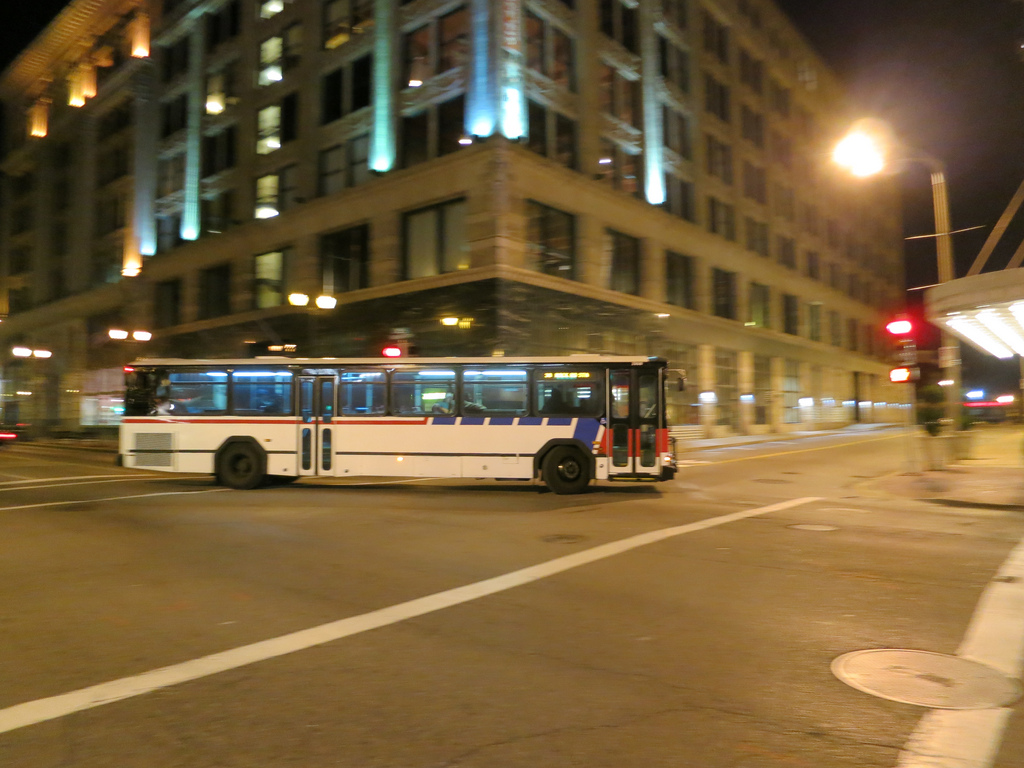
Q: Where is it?
A: This is at the city.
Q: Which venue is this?
A: This is a city.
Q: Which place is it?
A: It is a city.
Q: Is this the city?
A: Yes, it is the city.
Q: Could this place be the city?
A: Yes, it is the city.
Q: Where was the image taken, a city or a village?
A: It was taken at a city.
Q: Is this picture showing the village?
A: No, the picture is showing the city.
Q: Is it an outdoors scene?
A: Yes, it is outdoors.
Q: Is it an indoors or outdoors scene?
A: It is outdoors.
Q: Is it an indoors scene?
A: No, it is outdoors.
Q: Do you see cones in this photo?
A: No, there are no cones.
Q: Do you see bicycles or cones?
A: No, there are no cones or bicycles.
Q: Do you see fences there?
A: No, there are no fences.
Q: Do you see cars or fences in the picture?
A: No, there are no fences or cars.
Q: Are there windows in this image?
A: Yes, there is a window.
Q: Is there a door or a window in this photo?
A: Yes, there is a window.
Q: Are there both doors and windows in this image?
A: Yes, there are both a window and a door.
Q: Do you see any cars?
A: No, there are no cars.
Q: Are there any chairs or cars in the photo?
A: No, there are no cars or chairs.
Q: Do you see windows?
A: Yes, there is a window.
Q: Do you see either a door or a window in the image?
A: Yes, there is a window.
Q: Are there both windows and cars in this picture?
A: No, there is a window but no cars.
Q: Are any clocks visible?
A: No, there are no clocks.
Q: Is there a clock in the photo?
A: No, there are no clocks.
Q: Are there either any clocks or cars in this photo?
A: No, there are no clocks or cars.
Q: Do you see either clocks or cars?
A: No, there are no clocks or cars.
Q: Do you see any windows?
A: Yes, there is a window.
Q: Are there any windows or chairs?
A: Yes, there is a window.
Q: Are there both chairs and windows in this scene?
A: No, there is a window but no chairs.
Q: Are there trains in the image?
A: No, there are no trains.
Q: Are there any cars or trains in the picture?
A: No, there are no trains or cars.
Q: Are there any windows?
A: Yes, there is a window.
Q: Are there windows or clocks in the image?
A: Yes, there is a window.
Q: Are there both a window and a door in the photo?
A: Yes, there are both a window and a door.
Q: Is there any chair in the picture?
A: No, there are no chairs.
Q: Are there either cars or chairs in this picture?
A: No, there are no chairs or cars.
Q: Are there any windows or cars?
A: Yes, there is a window.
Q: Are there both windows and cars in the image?
A: No, there is a window but no cars.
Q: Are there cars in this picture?
A: No, there are no cars.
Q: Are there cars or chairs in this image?
A: No, there are no cars or chairs.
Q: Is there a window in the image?
A: Yes, there is a window.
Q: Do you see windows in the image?
A: Yes, there is a window.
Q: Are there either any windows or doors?
A: Yes, there is a window.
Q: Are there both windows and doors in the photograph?
A: Yes, there are both a window and a door.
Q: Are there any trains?
A: No, there are no trains.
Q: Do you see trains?
A: No, there are no trains.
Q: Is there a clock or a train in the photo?
A: No, there are no trains or clocks.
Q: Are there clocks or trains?
A: No, there are no trains or clocks.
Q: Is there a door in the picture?
A: Yes, there is a door.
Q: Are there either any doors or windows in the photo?
A: Yes, there is a door.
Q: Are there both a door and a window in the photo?
A: Yes, there are both a door and a window.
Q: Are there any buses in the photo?
A: Yes, there is a bus.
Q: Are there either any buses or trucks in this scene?
A: Yes, there is a bus.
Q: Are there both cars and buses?
A: No, there is a bus but no cars.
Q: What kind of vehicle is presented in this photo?
A: The vehicle is a bus.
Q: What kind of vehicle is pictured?
A: The vehicle is a bus.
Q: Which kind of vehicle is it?
A: The vehicle is a bus.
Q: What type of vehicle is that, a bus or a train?
A: This is a bus.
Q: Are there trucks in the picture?
A: No, there are no trucks.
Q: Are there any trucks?
A: No, there are no trucks.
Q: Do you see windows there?
A: Yes, there is a window.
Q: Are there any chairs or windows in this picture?
A: Yes, there is a window.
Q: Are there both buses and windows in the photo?
A: Yes, there are both a window and a bus.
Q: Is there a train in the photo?
A: No, there are no trains.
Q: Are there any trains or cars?
A: No, there are no trains or cars.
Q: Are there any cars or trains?
A: No, there are no trains or cars.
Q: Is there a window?
A: Yes, there is a window.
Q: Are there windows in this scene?
A: Yes, there is a window.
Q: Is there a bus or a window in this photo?
A: Yes, there is a window.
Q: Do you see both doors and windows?
A: Yes, there are both a window and a door.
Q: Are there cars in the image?
A: No, there are no cars.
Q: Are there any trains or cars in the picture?
A: No, there are no cars or trains.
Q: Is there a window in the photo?
A: Yes, there is a window.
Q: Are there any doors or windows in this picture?
A: Yes, there is a window.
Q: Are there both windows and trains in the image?
A: No, there is a window but no trains.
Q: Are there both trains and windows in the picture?
A: No, there is a window but no trains.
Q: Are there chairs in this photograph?
A: No, there are no chairs.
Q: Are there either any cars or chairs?
A: No, there are no chairs or cars.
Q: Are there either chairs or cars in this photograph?
A: No, there are no chairs or cars.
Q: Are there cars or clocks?
A: No, there are no cars or clocks.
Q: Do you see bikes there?
A: No, there are no bikes.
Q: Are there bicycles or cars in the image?
A: No, there are no bicycles or cars.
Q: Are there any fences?
A: No, there are no fences.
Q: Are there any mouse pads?
A: No, there are no mouse pads.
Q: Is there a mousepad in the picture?
A: No, there are no mouse pads.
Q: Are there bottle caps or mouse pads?
A: No, there are no mouse pads or bottle caps.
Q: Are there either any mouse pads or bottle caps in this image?
A: No, there are no mouse pads or bottle caps.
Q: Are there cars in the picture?
A: No, there are no cars.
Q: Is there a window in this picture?
A: Yes, there is a window.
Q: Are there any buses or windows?
A: Yes, there is a window.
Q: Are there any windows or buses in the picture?
A: Yes, there is a window.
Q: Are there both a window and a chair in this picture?
A: No, there is a window but no chairs.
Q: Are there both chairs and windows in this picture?
A: No, there is a window but no chairs.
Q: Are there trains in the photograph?
A: No, there are no trains.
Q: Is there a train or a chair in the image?
A: No, there are no trains or chairs.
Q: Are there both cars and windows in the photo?
A: No, there is a window but no cars.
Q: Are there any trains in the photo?
A: No, there are no trains.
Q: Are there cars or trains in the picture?
A: No, there are no trains or cars.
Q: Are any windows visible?
A: Yes, there is a window.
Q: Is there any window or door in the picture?
A: Yes, there is a window.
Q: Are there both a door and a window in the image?
A: Yes, there are both a window and a door.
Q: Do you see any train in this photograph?
A: No, there are no trains.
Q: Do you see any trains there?
A: No, there are no trains.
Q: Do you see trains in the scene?
A: No, there are no trains.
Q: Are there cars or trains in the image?
A: No, there are no trains or cars.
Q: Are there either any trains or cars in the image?
A: No, there are no trains or cars.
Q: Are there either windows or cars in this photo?
A: Yes, there is a window.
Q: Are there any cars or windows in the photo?
A: Yes, there is a window.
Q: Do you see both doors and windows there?
A: Yes, there are both a window and a door.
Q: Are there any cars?
A: No, there are no cars.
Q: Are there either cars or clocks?
A: No, there are no cars or clocks.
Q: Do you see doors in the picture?
A: Yes, there is a door.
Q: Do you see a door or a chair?
A: Yes, there is a door.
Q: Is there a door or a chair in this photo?
A: Yes, there is a door.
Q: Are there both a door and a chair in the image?
A: No, there is a door but no chairs.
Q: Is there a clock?
A: No, there are no clocks.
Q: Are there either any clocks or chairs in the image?
A: No, there are no clocks or chairs.